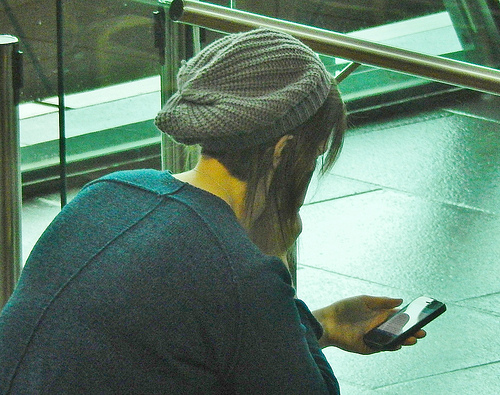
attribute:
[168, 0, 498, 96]
tilted pole — melted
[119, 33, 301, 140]
hat — brown, knit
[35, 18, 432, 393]
woman — Gray, knit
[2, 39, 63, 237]
post — metal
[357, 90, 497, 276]
floor — shiny, white, tiled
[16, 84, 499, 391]
tile floor — gray, ceramic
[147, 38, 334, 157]
hat — gray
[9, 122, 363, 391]
sweater — gray, blue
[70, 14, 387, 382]
girl — texting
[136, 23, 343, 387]
girl — socializing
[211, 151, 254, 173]
hair — short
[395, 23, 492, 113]
pole — metal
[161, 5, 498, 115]
hand rail — shiny, metal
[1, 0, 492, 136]
window — glass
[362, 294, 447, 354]
phone — black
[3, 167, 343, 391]
shirt — gray, blue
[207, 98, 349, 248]
hair — Brown 